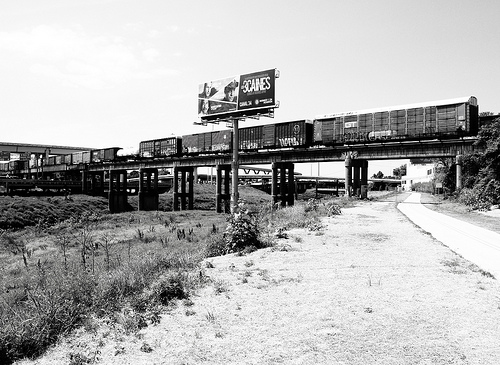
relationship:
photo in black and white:
[11, 35, 488, 297] [224, 78, 250, 102]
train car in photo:
[319, 98, 486, 140] [11, 35, 488, 297]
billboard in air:
[193, 75, 279, 116] [60, 47, 113, 64]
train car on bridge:
[319, 98, 486, 140] [284, 141, 453, 159]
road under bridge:
[406, 198, 463, 244] [284, 141, 453, 159]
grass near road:
[148, 225, 268, 244] [406, 198, 463, 244]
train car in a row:
[319, 98, 486, 140] [138, 107, 475, 161]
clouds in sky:
[466, 28, 491, 73] [95, 38, 169, 72]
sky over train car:
[95, 38, 169, 72] [319, 98, 486, 140]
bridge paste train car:
[284, 141, 453, 159] [319, 98, 486, 140]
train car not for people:
[319, 98, 486, 140] [201, 84, 241, 113]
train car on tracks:
[319, 98, 486, 140] [114, 154, 139, 165]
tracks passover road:
[114, 154, 139, 165] [406, 198, 463, 244]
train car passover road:
[319, 98, 486, 140] [406, 198, 463, 244]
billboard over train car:
[193, 75, 279, 116] [319, 98, 486, 140]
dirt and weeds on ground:
[186, 267, 221, 295] [287, 204, 336, 251]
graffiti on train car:
[279, 136, 299, 146] [319, 98, 486, 140]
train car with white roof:
[319, 98, 486, 140] [418, 95, 473, 110]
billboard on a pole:
[193, 75, 279, 116] [230, 120, 242, 219]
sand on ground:
[219, 256, 237, 277] [287, 204, 336, 251]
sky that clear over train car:
[95, 38, 169, 72] [319, 98, 486, 140]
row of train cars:
[138, 107, 475, 161] [244, 116, 465, 145]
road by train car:
[406, 198, 463, 244] [319, 98, 486, 140]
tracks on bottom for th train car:
[114, 154, 139, 165] [319, 98, 486, 140]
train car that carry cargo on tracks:
[319, 98, 486, 140] [114, 154, 139, 165]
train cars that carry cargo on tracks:
[244, 116, 465, 145] [114, 154, 139, 165]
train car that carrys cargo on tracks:
[319, 98, 486, 140] [114, 154, 139, 165]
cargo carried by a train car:
[189, 131, 227, 153] [319, 98, 486, 140]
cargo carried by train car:
[189, 131, 227, 153] [319, 98, 486, 140]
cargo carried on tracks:
[189, 131, 227, 153] [114, 154, 139, 165]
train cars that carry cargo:
[244, 116, 465, 145] [189, 131, 227, 153]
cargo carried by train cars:
[189, 131, 227, 153] [244, 116, 465, 145]